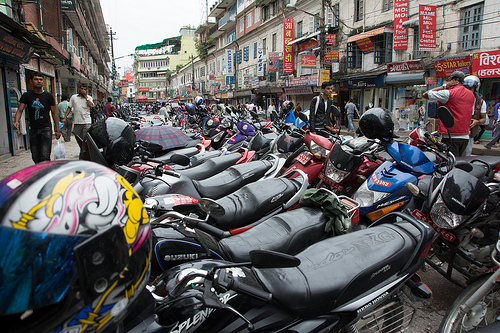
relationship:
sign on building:
[420, 5, 439, 51] [135, 25, 213, 91]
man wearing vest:
[439, 66, 481, 162] [441, 83, 481, 138]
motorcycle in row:
[142, 145, 308, 178] [117, 110, 484, 285]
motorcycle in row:
[142, 145, 308, 178] [78, 107, 443, 330]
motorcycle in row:
[142, 145, 308, 178] [114, 106, 456, 328]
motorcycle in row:
[142, 145, 308, 178] [100, 114, 464, 331]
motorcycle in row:
[142, 145, 308, 178] [105, 126, 484, 331]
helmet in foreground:
[6, 156, 160, 299] [5, 134, 235, 331]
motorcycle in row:
[142, 145, 308, 178] [110, 113, 498, 333]